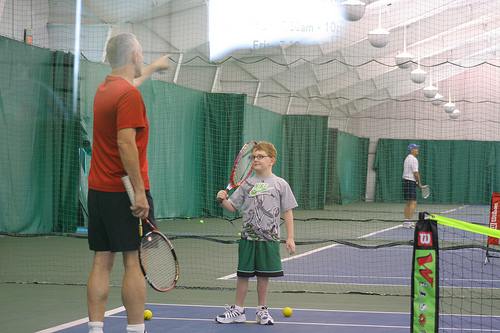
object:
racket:
[120, 174, 180, 291]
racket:
[216, 140, 258, 204]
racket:
[414, 182, 431, 199]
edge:
[169, 251, 179, 286]